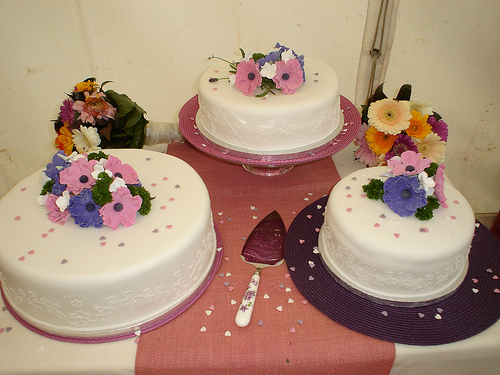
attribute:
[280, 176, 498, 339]
mat — purple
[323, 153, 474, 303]
cake — white, creamy, decorated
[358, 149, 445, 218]
flowers — pink, icing, blue, colorful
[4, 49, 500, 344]
cakes — white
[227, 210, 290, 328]
spatula — small, creamy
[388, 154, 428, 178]
flower — pink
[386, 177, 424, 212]
flower — purple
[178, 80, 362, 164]
plate — pink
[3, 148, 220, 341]
cake — large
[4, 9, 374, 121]
wall — white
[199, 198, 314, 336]
confetti — decoration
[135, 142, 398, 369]
runner — pink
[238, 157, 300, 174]
stand — pedestal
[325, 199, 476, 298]
fondant — white